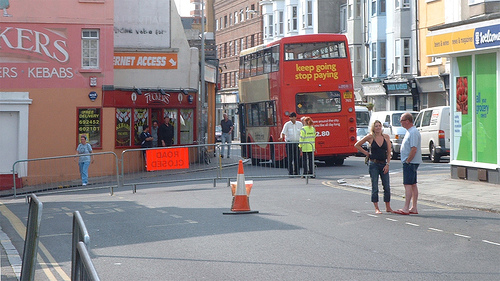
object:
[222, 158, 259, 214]
traffic cone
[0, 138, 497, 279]
road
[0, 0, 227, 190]
brick building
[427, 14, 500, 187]
building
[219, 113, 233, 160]
man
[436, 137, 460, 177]
ground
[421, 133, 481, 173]
ground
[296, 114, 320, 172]
woman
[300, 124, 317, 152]
safety shirt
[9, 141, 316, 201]
barricade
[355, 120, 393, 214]
people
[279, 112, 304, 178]
people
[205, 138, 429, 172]
street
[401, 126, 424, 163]
white shirt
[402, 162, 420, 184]
blue shorts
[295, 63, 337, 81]
sign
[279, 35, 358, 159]
back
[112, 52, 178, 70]
sign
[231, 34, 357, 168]
bus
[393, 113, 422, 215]
man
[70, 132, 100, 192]
person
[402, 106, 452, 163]
car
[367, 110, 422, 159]
car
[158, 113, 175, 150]
man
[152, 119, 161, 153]
man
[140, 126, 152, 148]
man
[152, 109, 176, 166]
door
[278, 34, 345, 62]
window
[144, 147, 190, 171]
sign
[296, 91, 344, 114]
window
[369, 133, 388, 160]
shirt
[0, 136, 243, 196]
sidewalk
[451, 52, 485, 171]
window